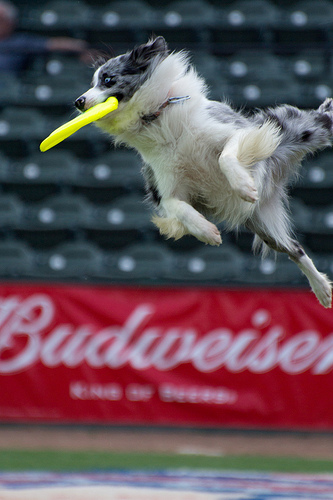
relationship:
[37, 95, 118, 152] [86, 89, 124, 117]
frisbee in mouth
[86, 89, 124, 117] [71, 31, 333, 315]
mouth on dog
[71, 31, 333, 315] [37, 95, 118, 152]
dog has frisbee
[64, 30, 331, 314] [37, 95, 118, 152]
dog playing with frisbee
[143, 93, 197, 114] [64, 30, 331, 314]
collar on dog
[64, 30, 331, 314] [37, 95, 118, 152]
dog catching frisbee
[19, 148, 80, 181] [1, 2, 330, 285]
seat in stands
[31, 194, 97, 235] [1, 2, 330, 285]
seat in stands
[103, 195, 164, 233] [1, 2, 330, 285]
seat in stands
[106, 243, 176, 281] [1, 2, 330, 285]
seat in stands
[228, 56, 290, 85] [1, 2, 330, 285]
seat in stands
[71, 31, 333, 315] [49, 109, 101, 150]
dog catching frisbee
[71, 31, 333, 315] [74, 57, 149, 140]
dog has face